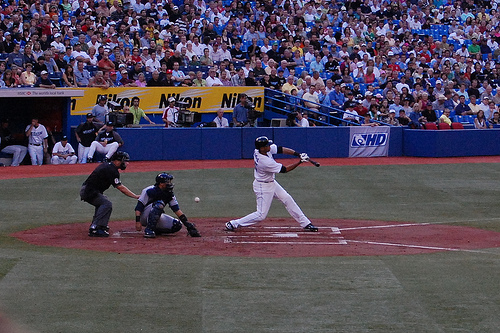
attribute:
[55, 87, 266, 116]
banner — bright yellow, yellow, advertising, black, advertisement, for nikon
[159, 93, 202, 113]
nikon — sponsor name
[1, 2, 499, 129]
stands — packed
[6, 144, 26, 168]
legs — bent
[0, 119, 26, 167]
man — invisible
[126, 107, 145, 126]
shirt — lime green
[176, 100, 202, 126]
video camera — large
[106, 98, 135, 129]
video camera — large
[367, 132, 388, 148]
hd — royal blue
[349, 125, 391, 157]
banner — small, square, blue grey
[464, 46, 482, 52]
shirt — short sleeved, kelly green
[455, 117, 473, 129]
seat — empty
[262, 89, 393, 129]
rails — blue, metal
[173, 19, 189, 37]
outfit — black, striped, prison like, white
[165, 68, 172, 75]
baseball cap — red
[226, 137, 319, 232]
baseball player — batter, moving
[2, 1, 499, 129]
spectators — fans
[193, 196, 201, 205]
baseball — in air, white, flying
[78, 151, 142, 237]
umpire — standing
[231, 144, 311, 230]
uniform — white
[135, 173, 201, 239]
catcher — kneeling, crouched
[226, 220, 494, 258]
lines — white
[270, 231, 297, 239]
homeplate — white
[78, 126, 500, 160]
wall — blue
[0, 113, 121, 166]
players — watching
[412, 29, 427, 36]
seat — empty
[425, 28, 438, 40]
seat — empty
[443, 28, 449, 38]
seat — empty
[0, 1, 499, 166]
stadium — outdoors, man-made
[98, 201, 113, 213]
knees — bent